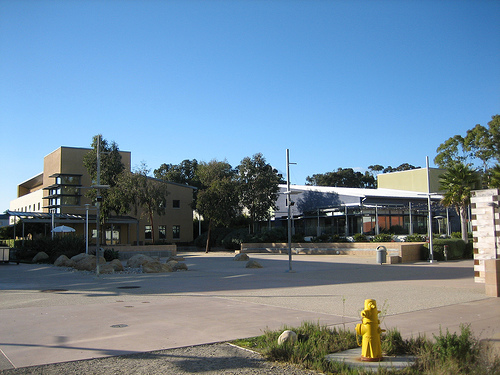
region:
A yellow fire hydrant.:
[355, 300, 387, 361]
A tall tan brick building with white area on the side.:
[6, 144, 198, 248]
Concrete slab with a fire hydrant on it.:
[323, 342, 425, 373]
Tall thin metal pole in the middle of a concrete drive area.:
[283, 147, 293, 273]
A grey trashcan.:
[375, 244, 389, 264]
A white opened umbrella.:
[51, 224, 77, 234]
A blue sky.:
[1, 1, 498, 190]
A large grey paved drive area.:
[1, 249, 469, 371]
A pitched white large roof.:
[277, 179, 447, 201]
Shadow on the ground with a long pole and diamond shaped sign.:
[2, 339, 271, 374]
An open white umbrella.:
[51, 222, 74, 234]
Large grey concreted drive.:
[3, 250, 490, 370]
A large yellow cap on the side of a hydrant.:
[353, 323, 362, 339]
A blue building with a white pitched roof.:
[273, 182, 445, 228]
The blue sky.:
[1, 2, 498, 172]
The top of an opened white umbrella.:
[51, 224, 74, 234]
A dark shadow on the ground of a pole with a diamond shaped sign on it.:
[1, 341, 267, 374]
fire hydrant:
[360, 284, 403, 372]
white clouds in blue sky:
[32, 19, 92, 64]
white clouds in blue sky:
[268, 66, 293, 81]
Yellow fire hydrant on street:
[356, 295, 390, 361]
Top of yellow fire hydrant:
[357, 295, 381, 305]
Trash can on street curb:
[373, 243, 386, 263]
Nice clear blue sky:
[38, 108, 105, 128]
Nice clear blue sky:
[196, 22, 282, 74]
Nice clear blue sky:
[326, 18, 450, 69]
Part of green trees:
[201, 176, 239, 216]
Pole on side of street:
[276, 140, 301, 269]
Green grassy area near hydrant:
[299, 339, 333, 356]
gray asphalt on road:
[188, 288, 235, 313]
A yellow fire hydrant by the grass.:
[351, 286, 390, 371]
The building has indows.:
[141, 194, 197, 244]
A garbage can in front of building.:
[368, 231, 389, 268]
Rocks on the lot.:
[84, 252, 184, 275]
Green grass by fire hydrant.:
[271, 310, 344, 355]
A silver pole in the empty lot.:
[267, 132, 301, 279]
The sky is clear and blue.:
[115, 27, 414, 126]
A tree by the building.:
[90, 153, 152, 242]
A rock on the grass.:
[258, 312, 309, 360]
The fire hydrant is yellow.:
[349, 284, 388, 359]